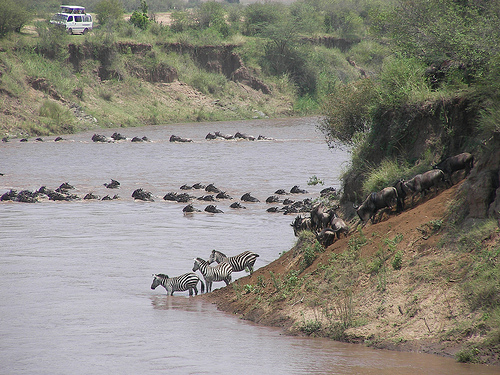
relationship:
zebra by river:
[149, 271, 204, 296] [0, 114, 498, 372]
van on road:
[48, 12, 94, 35] [92, 6, 204, 25]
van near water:
[48, 9, 95, 35] [0, 111, 498, 373]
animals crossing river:
[0, 176, 339, 226] [0, 114, 498, 372]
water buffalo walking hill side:
[352, 186, 404, 225] [303, 267, 421, 355]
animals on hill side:
[138, 133, 474, 304] [301, 260, 423, 344]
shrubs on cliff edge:
[375, 0, 497, 95] [338, 90, 499, 197]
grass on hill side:
[349, 242, 470, 299] [344, 251, 460, 360]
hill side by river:
[338, 250, 465, 334] [17, 119, 280, 373]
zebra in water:
[149, 271, 204, 296] [15, 242, 145, 361]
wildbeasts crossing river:
[3, 131, 475, 246] [0, 114, 498, 372]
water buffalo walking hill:
[353, 187, 395, 224] [351, 220, 392, 243]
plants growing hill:
[264, 233, 409, 294] [334, 256, 449, 346]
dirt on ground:
[213, 176, 498, 326] [208, 163, 496, 365]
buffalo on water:
[52, 155, 244, 216] [42, 264, 127, 372]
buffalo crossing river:
[58, 117, 275, 155] [61, 116, 228, 278]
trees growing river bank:
[384, 7, 495, 89] [135, 81, 233, 118]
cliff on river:
[0, 37, 392, 125] [0, 114, 498, 372]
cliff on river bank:
[0, 37, 392, 125] [0, 38, 384, 137]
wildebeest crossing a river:
[9, 178, 297, 221] [10, 130, 365, 373]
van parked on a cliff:
[48, 12, 94, 35] [0, 31, 393, 136]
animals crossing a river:
[6, 131, 341, 227] [4, 120, 320, 374]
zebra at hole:
[149, 271, 206, 299] [5, 114, 474, 372]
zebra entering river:
[192, 256, 234, 293] [0, 114, 498, 372]